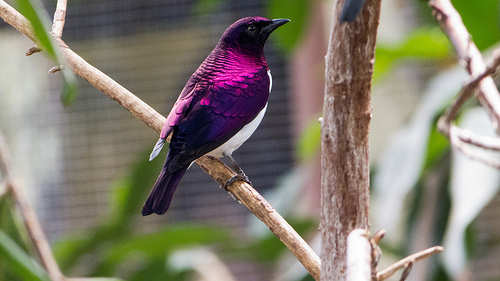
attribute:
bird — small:
[116, 17, 341, 195]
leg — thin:
[211, 150, 269, 190]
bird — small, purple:
[148, 13, 291, 203]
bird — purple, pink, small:
[139, 15, 292, 217]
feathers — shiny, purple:
[195, 58, 234, 100]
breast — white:
[208, 67, 273, 166]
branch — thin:
[3, 2, 323, 277]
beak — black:
[261, 11, 290, 40]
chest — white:
[205, 69, 277, 162]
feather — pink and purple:
[211, 70, 247, 80]